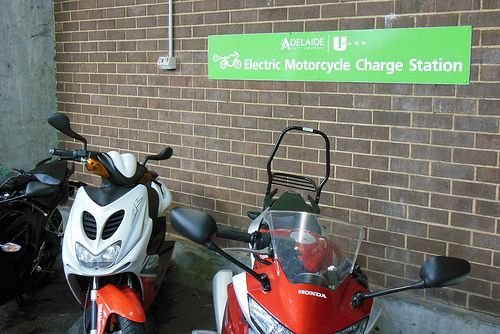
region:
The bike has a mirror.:
[383, 253, 475, 295]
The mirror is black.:
[400, 245, 474, 297]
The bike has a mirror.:
[160, 195, 259, 277]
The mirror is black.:
[160, 196, 246, 266]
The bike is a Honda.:
[283, 280, 342, 310]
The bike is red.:
[258, 280, 372, 330]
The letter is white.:
[282, 57, 296, 72]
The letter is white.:
[356, 59, 366, 75]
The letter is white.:
[404, 56, 418, 78]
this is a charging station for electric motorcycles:
[208, 23, 474, 88]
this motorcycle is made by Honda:
[287, 280, 338, 306]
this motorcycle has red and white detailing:
[208, 225, 383, 332]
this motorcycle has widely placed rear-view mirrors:
[166, 197, 472, 297]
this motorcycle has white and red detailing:
[50, 145, 175, 330]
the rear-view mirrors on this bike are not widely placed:
[43, 105, 175, 178]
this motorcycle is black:
[0, 135, 75, 302]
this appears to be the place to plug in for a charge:
[153, 53, 180, 73]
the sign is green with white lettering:
[203, 23, 474, 85]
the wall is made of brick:
[58, 8, 498, 306]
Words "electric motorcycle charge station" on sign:
[243, 56, 464, 78]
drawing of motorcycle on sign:
[208, 51, 241, 71]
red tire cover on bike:
[92, 281, 144, 332]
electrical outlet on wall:
[153, 56, 178, 72]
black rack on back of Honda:
[258, 117, 340, 196]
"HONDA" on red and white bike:
[296, 283, 328, 302]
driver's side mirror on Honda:
[419, 253, 473, 288]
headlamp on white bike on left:
[73, 239, 121, 271]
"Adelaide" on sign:
[277, 33, 326, 53]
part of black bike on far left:
[0, 160, 74, 297]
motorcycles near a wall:
[22, 9, 494, 316]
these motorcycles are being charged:
[28, 112, 493, 312]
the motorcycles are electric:
[27, 19, 472, 322]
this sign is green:
[194, 16, 484, 96]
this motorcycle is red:
[180, 129, 452, 332]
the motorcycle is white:
[58, 132, 173, 325]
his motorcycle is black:
[2, 127, 66, 309]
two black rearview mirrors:
[163, 194, 474, 311]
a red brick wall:
[99, 77, 238, 132]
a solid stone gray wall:
[7, 12, 54, 129]